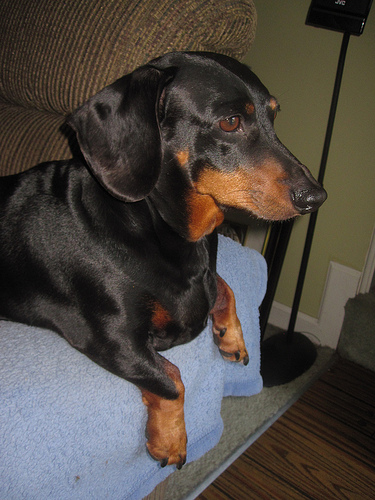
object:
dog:
[0, 49, 328, 471]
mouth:
[282, 191, 325, 223]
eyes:
[216, 108, 246, 135]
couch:
[0, 0, 258, 499]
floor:
[177, 356, 373, 500]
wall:
[239, 0, 374, 354]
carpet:
[140, 324, 336, 500]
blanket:
[1, 233, 268, 498]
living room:
[0, 0, 373, 497]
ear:
[61, 70, 164, 203]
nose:
[293, 180, 327, 211]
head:
[67, 49, 330, 235]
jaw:
[218, 204, 296, 230]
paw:
[212, 322, 248, 368]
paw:
[144, 414, 189, 470]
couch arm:
[1, 218, 239, 461]